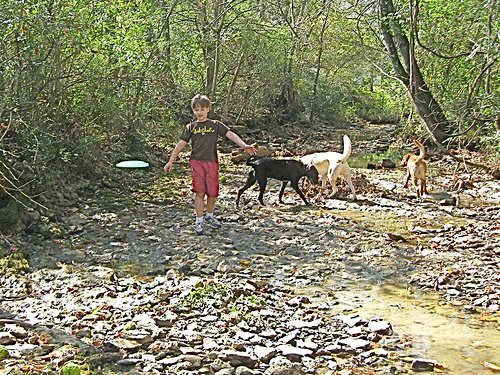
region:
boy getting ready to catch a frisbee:
[105, 90, 264, 237]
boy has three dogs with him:
[158, 90, 435, 241]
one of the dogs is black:
[233, 152, 322, 212]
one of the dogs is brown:
[396, 134, 431, 201]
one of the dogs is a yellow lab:
[296, 133, 363, 203]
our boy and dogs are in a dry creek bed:
[2, 85, 487, 373]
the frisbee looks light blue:
[108, 152, 155, 174]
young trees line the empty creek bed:
[1, 3, 370, 141]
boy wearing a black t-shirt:
[176, 115, 234, 170]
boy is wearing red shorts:
[184, 150, 226, 198]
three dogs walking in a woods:
[233, 133, 441, 215]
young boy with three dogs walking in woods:
[159, 88, 439, 235]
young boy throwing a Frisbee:
[113, 88, 274, 240]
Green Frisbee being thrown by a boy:
[113, 155, 161, 171]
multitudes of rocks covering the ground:
[0, 123, 497, 373]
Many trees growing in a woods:
[0, 0, 499, 152]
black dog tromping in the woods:
[231, 150, 328, 211]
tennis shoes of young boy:
[190, 210, 223, 237]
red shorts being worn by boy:
[191, 159, 224, 199]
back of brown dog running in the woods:
[396, 138, 438, 202]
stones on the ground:
[123, 302, 209, 367]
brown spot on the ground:
[378, 282, 455, 327]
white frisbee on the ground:
[101, 154, 158, 175]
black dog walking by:
[236, 148, 328, 208]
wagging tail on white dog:
[328, 125, 378, 173]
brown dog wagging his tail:
[400, 144, 436, 204]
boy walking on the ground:
[146, 82, 256, 219]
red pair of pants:
[181, 151, 229, 197]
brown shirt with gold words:
[174, 109, 243, 168]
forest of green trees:
[114, 25, 446, 95]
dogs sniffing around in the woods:
[270, 128, 454, 214]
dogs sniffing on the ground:
[273, 128, 459, 213]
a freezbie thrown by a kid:
[96, 128, 240, 212]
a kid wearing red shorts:
[188, 159, 238, 206]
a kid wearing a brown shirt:
[167, 103, 237, 168]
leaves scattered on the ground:
[90, 205, 472, 305]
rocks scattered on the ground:
[93, 272, 253, 373]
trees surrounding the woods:
[43, 27, 415, 91]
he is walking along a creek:
[156, 67, 259, 258]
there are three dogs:
[231, 109, 447, 231]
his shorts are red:
[178, 151, 228, 203]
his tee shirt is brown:
[172, 117, 239, 168]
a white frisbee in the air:
[102, 143, 164, 175]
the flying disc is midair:
[106, 144, 178, 185]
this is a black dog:
[232, 140, 324, 217]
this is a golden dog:
[297, 127, 382, 200]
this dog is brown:
[392, 106, 473, 228]